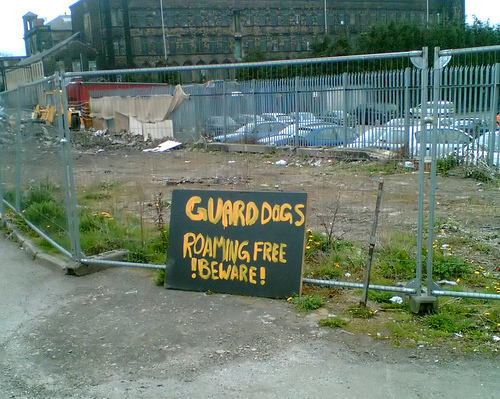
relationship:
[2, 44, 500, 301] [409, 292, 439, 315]
fence on cinder blocks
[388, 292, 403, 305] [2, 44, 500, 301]
trash near fence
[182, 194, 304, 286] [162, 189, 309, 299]
writing on sign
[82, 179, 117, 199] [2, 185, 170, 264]
patch of grass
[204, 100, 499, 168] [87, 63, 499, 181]
cars behind a fence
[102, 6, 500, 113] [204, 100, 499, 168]
trees behind cars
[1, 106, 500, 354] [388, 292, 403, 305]
field with garbage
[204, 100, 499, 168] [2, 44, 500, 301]
cars behind fence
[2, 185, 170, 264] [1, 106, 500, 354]
grass in field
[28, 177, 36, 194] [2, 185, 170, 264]
flower on top of grass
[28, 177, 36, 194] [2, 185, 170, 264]
flower on grass